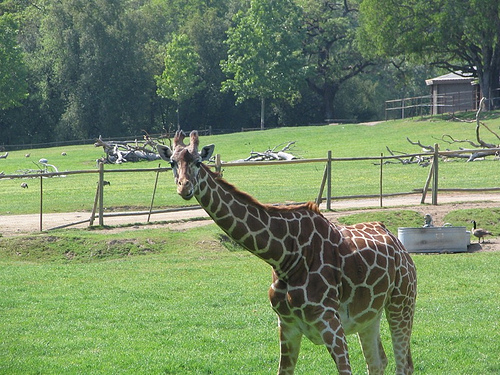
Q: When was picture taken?
A: During daylight.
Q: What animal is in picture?
A: Giraff.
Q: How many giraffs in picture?
A: One.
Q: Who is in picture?
A: None.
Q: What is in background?
A: Trees.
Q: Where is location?
A: A zoo setting.